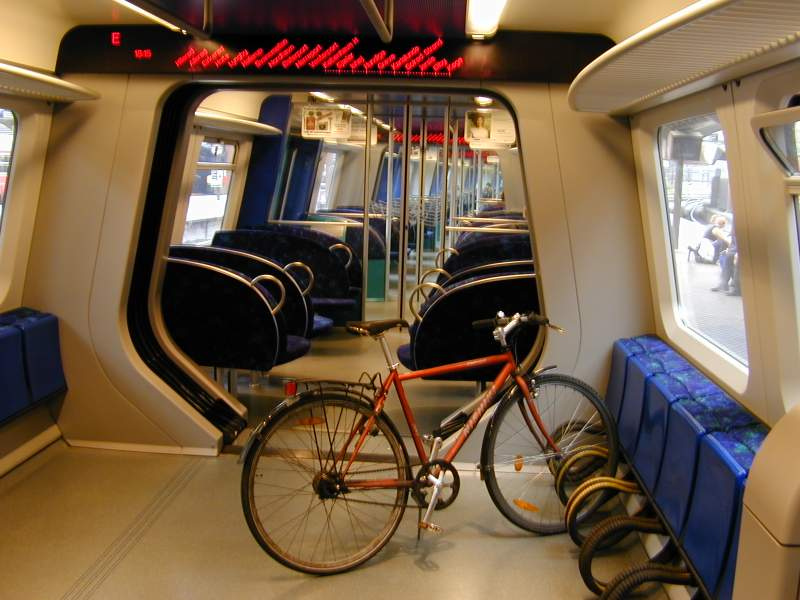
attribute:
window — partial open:
[750, 102, 793, 176]